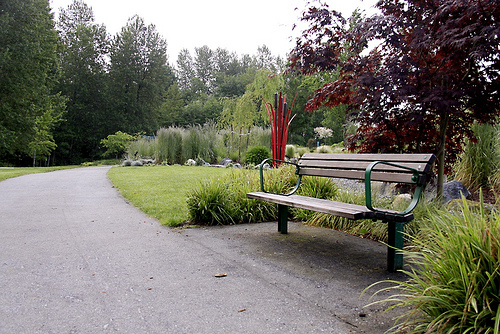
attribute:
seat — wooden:
[245, 189, 415, 224]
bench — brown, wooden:
[244, 149, 438, 271]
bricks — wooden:
[245, 146, 445, 251]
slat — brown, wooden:
[246, 189, 365, 224]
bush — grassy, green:
[350, 184, 499, 331]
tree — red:
[341, 62, 408, 142]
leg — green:
[246, 152, 423, 317]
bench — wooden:
[225, 104, 443, 249]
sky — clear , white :
[144, 0, 284, 55]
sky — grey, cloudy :
[50, 0, 412, 60]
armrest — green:
[363, 153, 428, 220]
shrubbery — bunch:
[185, 119, 496, 330]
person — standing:
[309, 129, 331, 150]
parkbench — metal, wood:
[235, 131, 444, 280]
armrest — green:
[253, 152, 305, 197]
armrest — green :
[364, 160, 421, 215]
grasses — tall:
[190, 161, 492, 323]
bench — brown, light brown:
[249, 147, 434, 281]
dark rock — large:
[428, 180, 473, 209]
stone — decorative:
[230, 161, 242, 168]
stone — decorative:
[221, 162, 235, 168]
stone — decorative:
[185, 157, 198, 167]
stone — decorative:
[118, 158, 134, 168]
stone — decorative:
[128, 158, 143, 167]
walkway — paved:
[5, 161, 248, 326]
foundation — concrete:
[187, 207, 427, 317]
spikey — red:
[262, 90, 294, 177]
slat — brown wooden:
[296, 156, 430, 181]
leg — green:
[386, 222, 409, 272]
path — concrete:
[63, 145, 390, 314]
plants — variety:
[160, 129, 193, 162]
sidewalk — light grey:
[1, 166, 354, 331]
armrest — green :
[258, 156, 303, 191]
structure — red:
[258, 84, 308, 158]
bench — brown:
[251, 133, 385, 215]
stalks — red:
[261, 91, 306, 169]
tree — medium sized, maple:
[280, 3, 497, 208]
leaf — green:
[473, 181, 485, 215]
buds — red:
[296, 36, 481, 152]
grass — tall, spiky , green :
[132, 149, 498, 331]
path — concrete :
[0, 163, 398, 332]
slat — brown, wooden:
[296, 163, 420, 182]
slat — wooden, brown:
[253, 190, 363, 217]